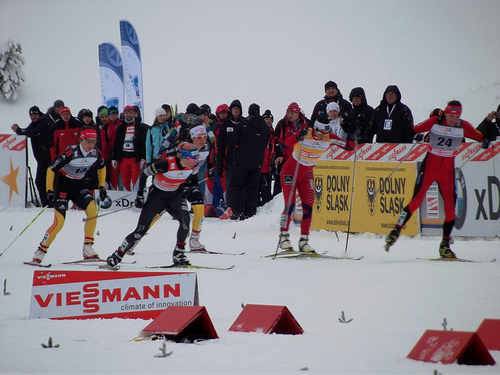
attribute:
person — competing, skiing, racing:
[384, 100, 491, 258]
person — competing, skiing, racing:
[279, 114, 360, 254]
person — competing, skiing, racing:
[127, 122, 217, 250]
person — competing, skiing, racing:
[107, 143, 200, 268]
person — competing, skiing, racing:
[32, 125, 108, 263]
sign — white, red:
[29, 270, 201, 319]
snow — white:
[0, 176, 498, 375]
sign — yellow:
[310, 161, 420, 236]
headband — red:
[78, 129, 99, 141]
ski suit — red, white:
[396, 114, 485, 243]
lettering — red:
[34, 282, 182, 313]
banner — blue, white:
[119, 20, 145, 124]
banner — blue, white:
[99, 41, 124, 118]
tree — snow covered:
[1, 36, 27, 102]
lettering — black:
[313, 165, 406, 229]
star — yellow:
[0, 157, 21, 202]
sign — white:
[0, 134, 27, 209]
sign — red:
[141, 306, 220, 339]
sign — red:
[229, 304, 306, 335]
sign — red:
[408, 328, 496, 365]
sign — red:
[475, 318, 499, 350]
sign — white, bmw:
[93, 188, 148, 210]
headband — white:
[188, 125, 206, 139]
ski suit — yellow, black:
[40, 144, 108, 249]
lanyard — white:
[385, 101, 398, 131]